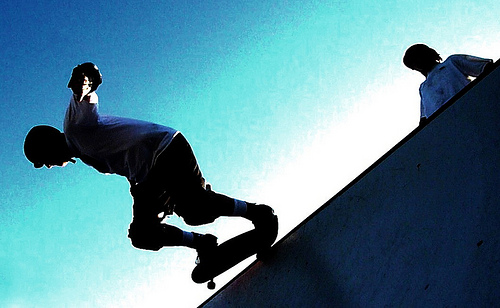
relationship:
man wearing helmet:
[17, 56, 282, 286] [15, 111, 65, 173]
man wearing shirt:
[24, 62, 277, 267] [63, 92, 182, 187]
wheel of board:
[206, 280, 217, 290] [191, 214, 280, 289]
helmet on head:
[15, 121, 65, 172] [19, 124, 71, 169]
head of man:
[19, 124, 71, 169] [24, 62, 277, 267]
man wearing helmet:
[24, 62, 277, 267] [15, 121, 65, 172]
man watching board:
[402, 42, 497, 126] [191, 214, 280, 289]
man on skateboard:
[24, 62, 277, 267] [190, 221, 280, 290]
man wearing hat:
[24, 62, 277, 267] [405, 43, 443, 58]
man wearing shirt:
[402, 42, 497, 126] [414, 49, 481, 115]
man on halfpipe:
[24, 62, 277, 267] [198, 58, 497, 306]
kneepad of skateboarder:
[125, 219, 171, 254] [11, 57, 279, 287]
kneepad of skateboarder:
[177, 187, 223, 227] [11, 57, 279, 287]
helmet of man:
[23, 124, 65, 170] [24, 62, 277, 267]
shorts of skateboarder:
[121, 133, 198, 253] [28, 46, 314, 286]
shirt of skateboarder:
[63, 100, 177, 192] [11, 57, 279, 287]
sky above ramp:
[3, 0, 406, 121] [206, 87, 497, 307]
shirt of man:
[410, 53, 471, 118] [402, 34, 499, 126]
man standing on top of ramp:
[402, 34, 499, 126] [201, 62, 498, 306]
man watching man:
[402, 42, 497, 126] [24, 62, 277, 267]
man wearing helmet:
[24, 62, 277, 267] [22, 117, 72, 172]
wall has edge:
[267, 97, 473, 260] [197, 58, 494, 305]